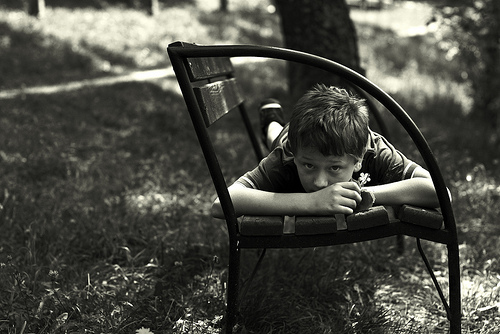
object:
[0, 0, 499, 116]
grass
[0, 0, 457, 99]
hill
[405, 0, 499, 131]
shrub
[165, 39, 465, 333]
bench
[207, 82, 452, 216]
boy